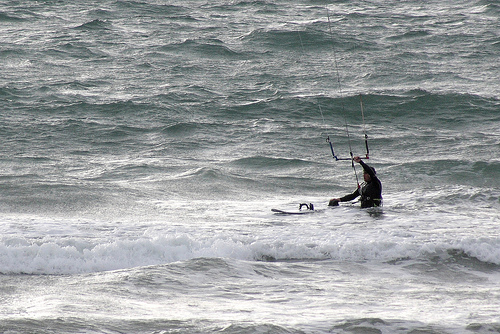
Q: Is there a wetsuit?
A: Yes, there is a wetsuit.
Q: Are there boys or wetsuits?
A: Yes, there is a wetsuit.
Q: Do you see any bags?
A: No, there are no bags.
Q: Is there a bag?
A: No, there are no bags.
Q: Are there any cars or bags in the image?
A: No, there are no bags or cars.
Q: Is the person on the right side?
A: Yes, the person is on the right of the image.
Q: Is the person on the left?
A: No, the person is on the right of the image.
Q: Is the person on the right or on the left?
A: The person is on the right of the image.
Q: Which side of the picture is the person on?
A: The person is on the right of the image.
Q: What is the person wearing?
A: The person is wearing a wetsuit.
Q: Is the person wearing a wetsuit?
A: Yes, the person is wearing a wetsuit.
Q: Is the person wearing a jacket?
A: No, the person is wearing a wetsuit.